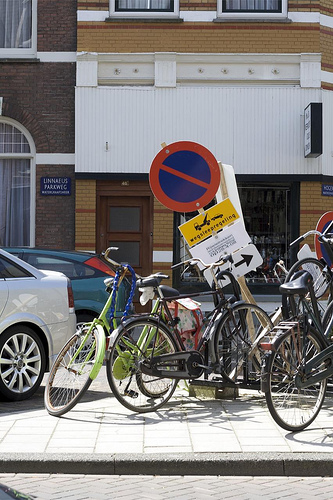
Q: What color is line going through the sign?
A: Red.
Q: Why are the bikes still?
A: They are parked.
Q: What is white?
A: The car.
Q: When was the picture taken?
A: Daytime.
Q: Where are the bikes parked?
A: Sidewalk.